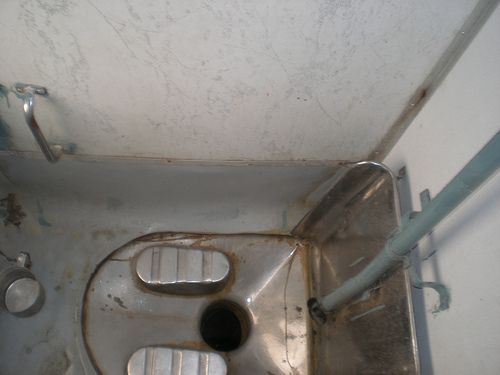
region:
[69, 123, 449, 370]
a dirty bathtub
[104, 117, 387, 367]
a dirty silver bathtub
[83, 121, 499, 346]
a dirty silver tub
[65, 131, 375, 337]
a dirty bathroom tub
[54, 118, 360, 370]
dirty silver metal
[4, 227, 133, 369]
a cup in the dirty tub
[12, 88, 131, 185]
a handle on the wall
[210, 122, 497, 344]
a pipe going up the wall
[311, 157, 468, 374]
a pipe connected to the wall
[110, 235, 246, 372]
Metal foot rests on floor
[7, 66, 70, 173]
Metal safety handle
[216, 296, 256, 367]
Drain in floor of metal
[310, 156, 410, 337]
Blue water pipe on wall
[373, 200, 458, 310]
Blue metal hinge for ipe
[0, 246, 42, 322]
Metal cup with handle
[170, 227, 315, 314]
Stains on floor of metal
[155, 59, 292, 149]
Wall in bathroom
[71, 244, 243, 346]
Slanted drain on metal floor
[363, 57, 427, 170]
Corner where two walls meet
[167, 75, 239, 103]
white wall in room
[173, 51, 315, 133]
design on the wall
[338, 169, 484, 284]
pole in the room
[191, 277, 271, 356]
hole on the ground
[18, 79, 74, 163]
bar on the wall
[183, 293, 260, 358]
circular hole on ground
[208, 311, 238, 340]
dark hole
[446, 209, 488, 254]
shadow on the wall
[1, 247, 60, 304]
silver cup on the ground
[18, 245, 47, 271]
handle of the cup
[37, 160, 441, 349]
a squat down toilet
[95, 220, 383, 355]
the toilet seat is metal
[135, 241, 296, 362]
there is a hole in the ground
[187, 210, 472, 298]
a pipe is up against the wall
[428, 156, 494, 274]
white painted walls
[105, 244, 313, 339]
you squat on the toilet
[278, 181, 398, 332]
the side of the walls are metal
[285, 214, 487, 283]
the pipe is green in color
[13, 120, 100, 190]
a chrome handle ball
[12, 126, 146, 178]
the bar is chrome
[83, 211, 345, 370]
Toilet made of metal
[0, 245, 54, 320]
Cup on the ground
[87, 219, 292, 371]
Toilet seat is old and rusty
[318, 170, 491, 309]
Blue pipe for plumbing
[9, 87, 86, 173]
Handle on the wall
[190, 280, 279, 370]
Hole is very deep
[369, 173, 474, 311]
Pipe anchored to the wall with a bracket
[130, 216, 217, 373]
Ovular shaped holes on the toilet seat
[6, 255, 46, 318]
The cup is empty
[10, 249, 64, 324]
The cup is in front of the toilet